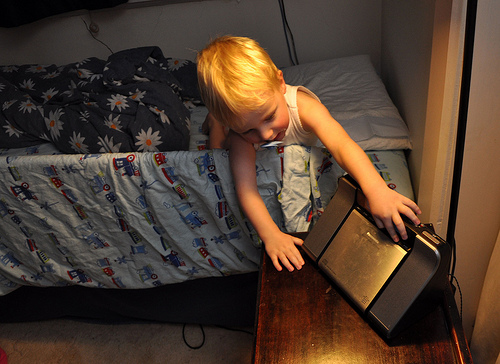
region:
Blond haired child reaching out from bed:
[191, 35, 425, 267]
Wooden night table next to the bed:
[255, 225, 459, 362]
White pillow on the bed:
[282, 57, 414, 153]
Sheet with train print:
[0, 151, 310, 294]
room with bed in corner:
[2, 1, 498, 361]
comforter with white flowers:
[1, 43, 201, 153]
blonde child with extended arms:
[197, 33, 422, 272]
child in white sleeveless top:
[196, 35, 421, 269]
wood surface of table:
[252, 231, 475, 362]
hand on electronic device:
[300, 171, 453, 341]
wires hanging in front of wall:
[0, 0, 384, 67]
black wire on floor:
[3, 320, 252, 362]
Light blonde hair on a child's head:
[194, 35, 272, 116]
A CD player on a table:
[302, 169, 449, 331]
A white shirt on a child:
[280, 92, 322, 152]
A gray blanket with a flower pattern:
[10, 46, 200, 148]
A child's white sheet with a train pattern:
[3, 149, 276, 302]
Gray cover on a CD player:
[316, 209, 404, 308]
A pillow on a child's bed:
[272, 50, 414, 157]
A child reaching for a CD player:
[188, 35, 422, 273]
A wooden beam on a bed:
[415, 0, 467, 239]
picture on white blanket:
[111, 152, 140, 179]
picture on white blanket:
[153, 150, 168, 165]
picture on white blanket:
[158, 165, 179, 185]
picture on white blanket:
[178, 208, 208, 230]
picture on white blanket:
[189, 233, 206, 248]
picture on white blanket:
[41, 163, 61, 179]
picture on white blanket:
[48, 176, 64, 188]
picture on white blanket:
[59, 187, 71, 197]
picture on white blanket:
[69, 265, 91, 287]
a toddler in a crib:
[1, 1, 448, 298]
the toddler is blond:
[168, 10, 436, 279]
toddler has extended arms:
[186, 26, 441, 288]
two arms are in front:
[191, 29, 433, 284]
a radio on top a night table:
[221, 166, 478, 360]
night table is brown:
[239, 264, 486, 362]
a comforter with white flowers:
[1, 34, 202, 166]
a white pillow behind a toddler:
[192, 5, 416, 185]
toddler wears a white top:
[183, 26, 418, 278]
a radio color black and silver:
[278, 164, 455, 335]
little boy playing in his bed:
[190, 35, 415, 277]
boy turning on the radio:
[181, 30, 438, 315]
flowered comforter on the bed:
[3, 48, 197, 146]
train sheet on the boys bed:
[9, 155, 206, 262]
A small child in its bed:
[182, 34, 425, 269]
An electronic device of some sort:
[297, 170, 454, 340]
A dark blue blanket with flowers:
[2, 41, 193, 155]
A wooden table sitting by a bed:
[249, 229, 474, 361]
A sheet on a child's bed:
[4, 143, 349, 300]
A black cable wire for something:
[276, 1, 305, 65]